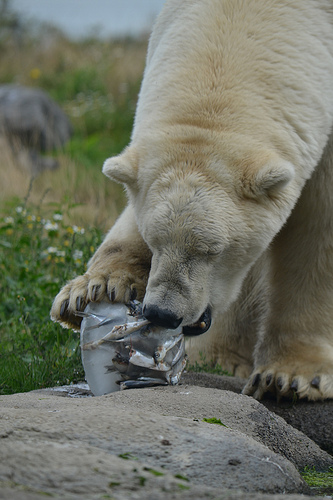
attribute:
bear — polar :
[100, 0, 331, 338]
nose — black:
[142, 303, 181, 329]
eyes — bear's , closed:
[150, 228, 218, 256]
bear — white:
[106, 0, 330, 400]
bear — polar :
[43, 48, 327, 337]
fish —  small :
[84, 288, 210, 401]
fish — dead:
[91, 318, 193, 385]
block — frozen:
[74, 297, 190, 398]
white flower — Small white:
[52, 214, 60, 220]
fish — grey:
[83, 313, 191, 390]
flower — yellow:
[19, 56, 50, 93]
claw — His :
[49, 267, 145, 335]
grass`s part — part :
[35, 358, 64, 384]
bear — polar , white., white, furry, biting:
[45, 14, 331, 395]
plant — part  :
[305, 471, 315, 492]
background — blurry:
[17, 4, 125, 143]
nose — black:
[144, 307, 181, 329]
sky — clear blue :
[0, 0, 166, 43]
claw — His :
[48, 271, 190, 384]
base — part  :
[78, 291, 190, 397]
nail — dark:
[58, 297, 68, 315]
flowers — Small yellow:
[43, 213, 84, 270]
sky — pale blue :
[31, 5, 134, 44]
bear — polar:
[109, 149, 284, 328]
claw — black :
[87, 283, 100, 304]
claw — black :
[262, 374, 270, 385]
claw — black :
[121, 284, 136, 304]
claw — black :
[289, 377, 297, 396]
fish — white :
[86, 304, 194, 388]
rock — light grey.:
[2, 387, 330, 495]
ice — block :
[80, 308, 181, 385]